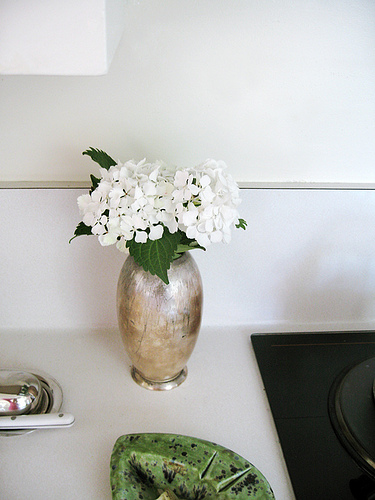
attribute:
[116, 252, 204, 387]
vase — filled, metallic, silver, oval, small, tarnished, brown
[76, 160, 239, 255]
flowers — white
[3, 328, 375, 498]
counter — white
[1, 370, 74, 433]
dish — silver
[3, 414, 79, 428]
flatware — white, knife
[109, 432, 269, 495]
dish — green, ceramic, leaf, glazed, clay, curved, leaf-shaped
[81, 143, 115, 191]
leaves — green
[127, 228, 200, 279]
leaves — green, large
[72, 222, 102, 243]
leaves — green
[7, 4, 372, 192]
wall — white, painted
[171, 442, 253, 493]
spots — black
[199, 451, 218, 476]
indent — long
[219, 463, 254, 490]
indent — long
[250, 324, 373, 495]
panel — black, stovetop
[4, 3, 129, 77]
cube — white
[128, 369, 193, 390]
base — small, round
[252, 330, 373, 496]
stove — black